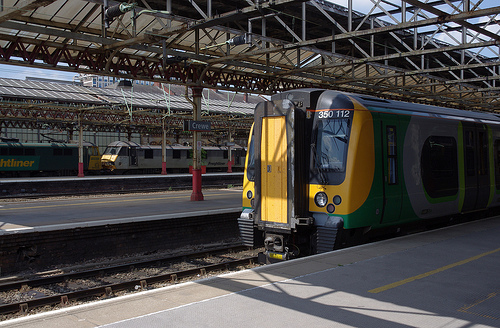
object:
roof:
[0, 75, 258, 116]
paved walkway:
[0, 189, 497, 328]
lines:
[368, 248, 500, 320]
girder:
[0, 0, 500, 114]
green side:
[328, 105, 500, 234]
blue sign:
[183, 120, 211, 132]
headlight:
[314, 191, 328, 207]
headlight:
[332, 195, 341, 205]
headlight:
[326, 203, 335, 213]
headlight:
[247, 190, 253, 199]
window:
[421, 135, 460, 198]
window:
[309, 118, 350, 186]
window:
[247, 126, 255, 180]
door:
[261, 116, 288, 224]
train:
[237, 87, 500, 266]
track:
[0, 241, 291, 319]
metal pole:
[189, 85, 204, 201]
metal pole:
[161, 129, 167, 175]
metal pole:
[227, 130, 233, 172]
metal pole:
[78, 125, 85, 177]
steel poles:
[76, 86, 232, 201]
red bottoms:
[78, 154, 235, 202]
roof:
[0, 0, 500, 114]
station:
[0, 0, 500, 328]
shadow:
[195, 216, 500, 328]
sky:
[324, 0, 500, 61]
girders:
[337, 3, 479, 55]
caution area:
[1, 213, 498, 328]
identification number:
[319, 110, 351, 119]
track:
[0, 182, 242, 199]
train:
[101, 140, 248, 175]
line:
[307, 108, 415, 116]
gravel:
[0, 234, 269, 320]